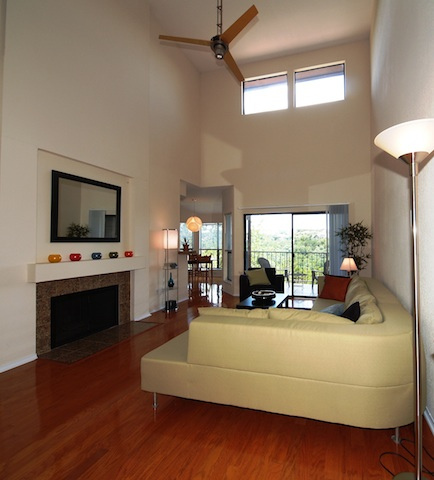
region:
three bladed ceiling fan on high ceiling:
[156, 0, 257, 83]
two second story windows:
[238, 59, 346, 117]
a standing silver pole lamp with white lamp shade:
[372, 117, 432, 477]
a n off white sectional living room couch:
[139, 276, 425, 444]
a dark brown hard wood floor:
[0, 295, 433, 477]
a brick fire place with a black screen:
[34, 271, 129, 357]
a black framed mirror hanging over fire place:
[49, 168, 122, 243]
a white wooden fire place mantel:
[28, 253, 145, 282]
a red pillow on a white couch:
[318, 272, 352, 303]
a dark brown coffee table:
[235, 289, 290, 310]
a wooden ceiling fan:
[153, 2, 271, 95]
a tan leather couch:
[136, 272, 423, 439]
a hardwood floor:
[1, 301, 432, 478]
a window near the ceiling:
[223, 49, 354, 121]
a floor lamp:
[366, 98, 432, 478]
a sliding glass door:
[243, 204, 347, 311]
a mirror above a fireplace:
[45, 165, 128, 251]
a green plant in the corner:
[329, 210, 378, 286]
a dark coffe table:
[234, 285, 292, 311]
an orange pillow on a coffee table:
[315, 270, 355, 303]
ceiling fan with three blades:
[155, 1, 259, 85]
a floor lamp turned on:
[365, 117, 431, 479]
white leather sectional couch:
[135, 273, 412, 447]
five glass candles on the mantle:
[35, 248, 157, 276]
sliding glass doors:
[241, 209, 334, 302]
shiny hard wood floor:
[0, 296, 428, 476]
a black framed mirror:
[46, 168, 122, 243]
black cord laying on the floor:
[372, 431, 432, 479]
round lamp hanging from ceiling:
[186, 189, 205, 235]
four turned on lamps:
[159, 113, 432, 424]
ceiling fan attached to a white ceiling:
[152, 7, 259, 86]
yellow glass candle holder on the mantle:
[47, 252, 61, 261]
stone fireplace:
[32, 268, 128, 355]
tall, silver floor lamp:
[368, 129, 432, 478]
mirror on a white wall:
[46, 167, 125, 246]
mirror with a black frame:
[48, 166, 126, 249]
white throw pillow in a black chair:
[243, 264, 270, 289]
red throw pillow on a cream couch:
[317, 274, 349, 300]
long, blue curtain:
[322, 199, 357, 278]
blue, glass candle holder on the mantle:
[89, 251, 102, 259]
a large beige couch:
[143, 268, 423, 436]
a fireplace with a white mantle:
[31, 256, 139, 357]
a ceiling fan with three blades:
[158, 1, 265, 80]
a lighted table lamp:
[339, 255, 356, 281]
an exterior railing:
[249, 248, 325, 284]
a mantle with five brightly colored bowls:
[31, 249, 144, 281]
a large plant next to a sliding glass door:
[340, 223, 371, 276]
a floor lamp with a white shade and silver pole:
[373, 134, 432, 478]